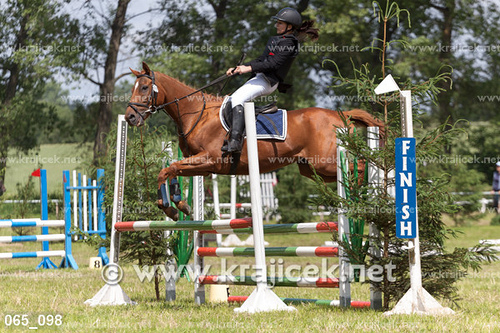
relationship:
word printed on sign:
[399, 136, 414, 236] [392, 136, 419, 239]